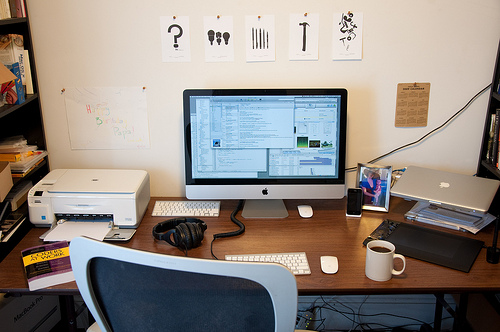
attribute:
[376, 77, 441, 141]
calendar — brown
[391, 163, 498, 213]
laptop — grey, white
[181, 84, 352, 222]
monitor — black, white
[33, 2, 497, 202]
wall — white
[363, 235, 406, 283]
mug — white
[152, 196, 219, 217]
keyboard — white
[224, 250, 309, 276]
keyboard — white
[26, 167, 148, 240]
printer — white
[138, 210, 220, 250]
headphones — black